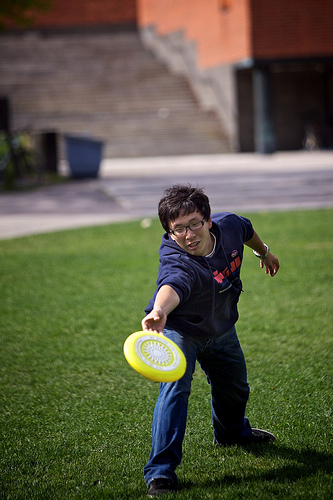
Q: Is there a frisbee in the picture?
A: Yes, there is a frisbee.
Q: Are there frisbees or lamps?
A: Yes, there is a frisbee.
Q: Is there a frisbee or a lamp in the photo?
A: Yes, there is a frisbee.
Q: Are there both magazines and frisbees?
A: No, there is a frisbee but no magazines.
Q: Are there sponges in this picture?
A: No, there are no sponges.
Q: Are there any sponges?
A: No, there are no sponges.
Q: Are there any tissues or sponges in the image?
A: No, there are no sponges or tissues.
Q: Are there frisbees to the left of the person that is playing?
A: Yes, there is a frisbee to the left of the person.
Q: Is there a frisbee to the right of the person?
A: No, the frisbee is to the left of the person.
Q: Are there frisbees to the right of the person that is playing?
A: No, the frisbee is to the left of the person.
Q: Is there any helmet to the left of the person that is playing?
A: No, there is a frisbee to the left of the person.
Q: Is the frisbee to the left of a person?
A: Yes, the frisbee is to the left of a person.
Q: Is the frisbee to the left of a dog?
A: No, the frisbee is to the left of a person.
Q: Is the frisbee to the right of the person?
A: No, the frisbee is to the left of the person.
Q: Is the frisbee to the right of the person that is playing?
A: No, the frisbee is to the left of the person.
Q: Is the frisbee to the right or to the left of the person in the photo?
A: The frisbee is to the left of the person.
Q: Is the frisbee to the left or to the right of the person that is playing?
A: The frisbee is to the left of the person.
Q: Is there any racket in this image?
A: No, there are no rackets.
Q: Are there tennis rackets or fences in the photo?
A: No, there are no tennis rackets or fences.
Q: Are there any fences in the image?
A: No, there are no fences.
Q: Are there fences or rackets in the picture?
A: No, there are no fences or rackets.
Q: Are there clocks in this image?
A: No, there are no clocks.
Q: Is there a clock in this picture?
A: No, there are no clocks.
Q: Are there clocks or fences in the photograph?
A: No, there are no clocks or fences.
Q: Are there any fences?
A: No, there are no fences.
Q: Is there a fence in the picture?
A: No, there are no fences.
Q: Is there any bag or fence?
A: No, there are no fences or bags.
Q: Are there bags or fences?
A: No, there are no fences or bags.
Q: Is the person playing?
A: Yes, the person is playing.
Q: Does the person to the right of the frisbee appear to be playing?
A: Yes, the person is playing.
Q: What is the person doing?
A: The person is playing.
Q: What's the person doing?
A: The person is playing.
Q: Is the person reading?
A: No, the person is playing.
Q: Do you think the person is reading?
A: No, the person is playing.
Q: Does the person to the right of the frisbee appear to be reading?
A: No, the person is playing.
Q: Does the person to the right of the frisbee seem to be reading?
A: No, the person is playing.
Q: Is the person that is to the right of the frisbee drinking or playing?
A: The person is playing.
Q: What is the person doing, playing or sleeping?
A: The person is playing.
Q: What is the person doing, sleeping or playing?
A: The person is playing.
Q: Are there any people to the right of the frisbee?
A: Yes, there is a person to the right of the frisbee.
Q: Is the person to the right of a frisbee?
A: Yes, the person is to the right of a frisbee.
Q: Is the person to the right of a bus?
A: No, the person is to the right of a frisbee.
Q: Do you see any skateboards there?
A: No, there are no skateboards.